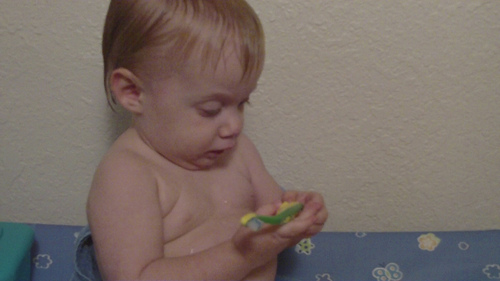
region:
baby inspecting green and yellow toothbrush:
[237, 190, 316, 230]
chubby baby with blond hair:
[81, 3, 337, 275]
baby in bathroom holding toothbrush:
[87, 0, 335, 272]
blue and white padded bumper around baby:
[2, 222, 498, 271]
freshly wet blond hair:
[97, 0, 270, 109]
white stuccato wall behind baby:
[7, 2, 498, 224]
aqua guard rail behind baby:
[0, 223, 47, 273]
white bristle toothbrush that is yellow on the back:
[236, 192, 311, 233]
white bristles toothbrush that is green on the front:
[237, 195, 309, 230]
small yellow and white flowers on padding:
[415, 230, 446, 252]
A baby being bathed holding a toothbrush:
[76, 2, 337, 275]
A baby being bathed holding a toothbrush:
[77, 2, 333, 272]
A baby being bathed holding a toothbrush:
[83, 5, 330, 275]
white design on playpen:
[412, 229, 441, 256]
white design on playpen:
[458, 240, 472, 252]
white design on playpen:
[479, 255, 498, 277]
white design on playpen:
[368, 259, 408, 279]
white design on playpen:
[313, 269, 333, 279]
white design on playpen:
[293, 235, 313, 259]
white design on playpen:
[71, 230, 80, 239]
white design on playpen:
[33, 252, 55, 269]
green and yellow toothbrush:
[203, 199, 370, 231]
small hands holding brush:
[201, 192, 363, 251]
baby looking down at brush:
[167, 80, 317, 265]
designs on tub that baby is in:
[358, 234, 498, 276]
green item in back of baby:
[0, 229, 35, 272]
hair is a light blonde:
[94, 6, 269, 75]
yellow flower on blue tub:
[406, 227, 461, 259]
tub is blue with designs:
[303, 234, 491, 279]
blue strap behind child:
[77, 220, 89, 280]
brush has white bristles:
[241, 212, 265, 240]